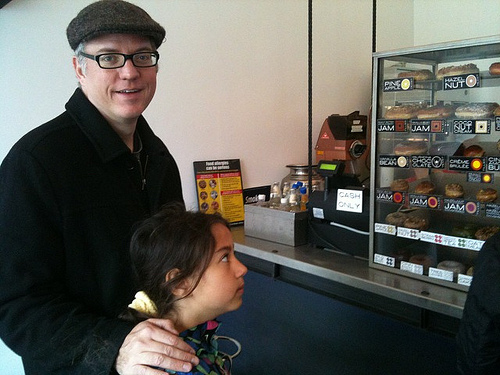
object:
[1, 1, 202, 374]
man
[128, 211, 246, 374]
girl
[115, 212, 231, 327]
hair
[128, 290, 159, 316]
scrunchie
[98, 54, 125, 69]
glasses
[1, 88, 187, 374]
jacket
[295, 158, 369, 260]
cash register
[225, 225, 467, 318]
counter top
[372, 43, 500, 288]
display case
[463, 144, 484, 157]
pastry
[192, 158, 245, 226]
sign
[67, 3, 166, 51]
hat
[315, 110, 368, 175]
coffee grinder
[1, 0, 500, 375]
wall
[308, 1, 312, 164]
line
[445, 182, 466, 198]
donuts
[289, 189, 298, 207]
glass jar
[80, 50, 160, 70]
eyeglasses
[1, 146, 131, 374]
arm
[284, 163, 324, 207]
vase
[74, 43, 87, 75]
hair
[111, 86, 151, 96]
smiling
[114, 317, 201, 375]
hand